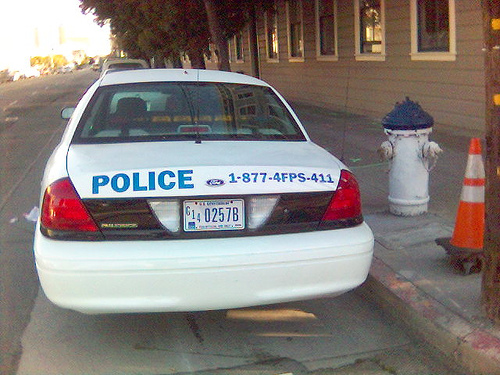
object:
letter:
[156, 169, 175, 190]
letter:
[147, 171, 156, 190]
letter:
[131, 172, 148, 191]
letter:
[175, 168, 193, 189]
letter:
[108, 173, 130, 193]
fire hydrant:
[376, 95, 442, 214]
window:
[74, 79, 304, 139]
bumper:
[27, 223, 377, 317]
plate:
[182, 198, 245, 231]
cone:
[448, 137, 487, 250]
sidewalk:
[277, 92, 498, 369]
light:
[316, 170, 364, 232]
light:
[39, 173, 106, 242]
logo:
[205, 179, 225, 187]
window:
[355, 0, 387, 61]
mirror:
[60, 104, 74, 120]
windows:
[408, 0, 456, 63]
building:
[160, 0, 493, 148]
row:
[190, 10, 457, 63]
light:
[14, 13, 88, 68]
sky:
[12, 11, 103, 71]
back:
[34, 67, 373, 313]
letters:
[289, 172, 297, 182]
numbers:
[326, 174, 335, 183]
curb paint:
[373, 242, 460, 334]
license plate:
[180, 198, 246, 232]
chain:
[422, 159, 440, 175]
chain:
[382, 160, 391, 173]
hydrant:
[376, 90, 442, 211]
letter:
[90, 168, 110, 197]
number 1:
[228, 172, 238, 183]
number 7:
[250, 172, 259, 183]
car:
[31, 67, 375, 318]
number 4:
[273, 172, 281, 183]